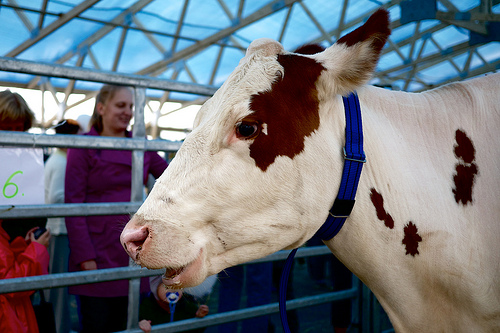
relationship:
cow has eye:
[117, 8, 499, 332] [236, 120, 258, 140]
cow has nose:
[117, 8, 499, 332] [119, 220, 150, 264]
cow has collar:
[117, 8, 499, 332] [306, 90, 366, 251]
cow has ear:
[117, 8, 499, 332] [325, 8, 390, 94]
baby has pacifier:
[138, 272, 210, 331] [166, 291, 179, 304]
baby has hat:
[138, 272, 210, 331] [148, 271, 181, 303]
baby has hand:
[138, 272, 210, 331] [195, 304, 211, 318]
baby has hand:
[138, 272, 210, 331] [139, 318, 153, 331]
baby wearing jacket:
[138, 272, 210, 331] [140, 291, 202, 331]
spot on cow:
[400, 222, 423, 258] [117, 8, 499, 332]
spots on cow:
[452, 128, 480, 206] [117, 8, 499, 332]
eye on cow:
[236, 120, 258, 140] [117, 8, 499, 332]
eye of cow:
[236, 120, 258, 140] [117, 8, 499, 332]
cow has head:
[117, 8, 499, 332] [118, 8, 390, 291]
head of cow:
[118, 8, 390, 291] [117, 8, 499, 332]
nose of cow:
[119, 220, 150, 264] [117, 8, 499, 332]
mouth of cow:
[147, 237, 206, 290] [117, 8, 499, 332]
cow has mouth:
[117, 8, 499, 332] [147, 237, 206, 290]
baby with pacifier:
[138, 272, 210, 331] [166, 291, 179, 304]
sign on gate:
[0, 145, 47, 206] [0, 56, 391, 331]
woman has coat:
[64, 83, 169, 331] [0, 220, 50, 332]